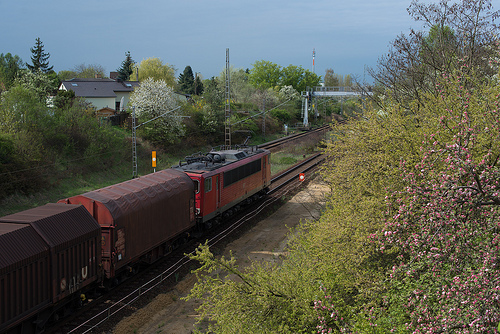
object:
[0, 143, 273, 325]
train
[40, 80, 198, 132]
neighborhood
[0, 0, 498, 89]
sky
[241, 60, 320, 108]
trees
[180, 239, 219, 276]
leaves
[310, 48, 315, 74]
tower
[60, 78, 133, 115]
house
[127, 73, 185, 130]
tree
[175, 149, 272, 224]
caboose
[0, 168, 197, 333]
last two cars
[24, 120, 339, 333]
tracks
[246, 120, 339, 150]
track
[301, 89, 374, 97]
bridge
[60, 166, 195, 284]
train car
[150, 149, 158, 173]
train sign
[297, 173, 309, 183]
train sign